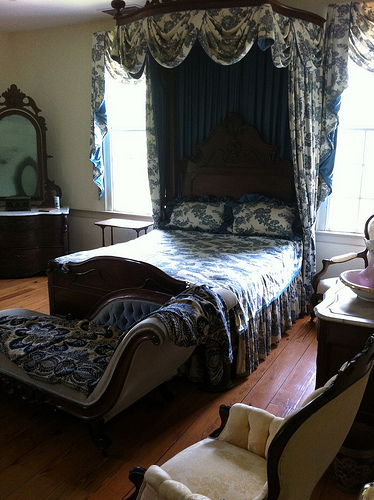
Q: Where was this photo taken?
A: A bedroom.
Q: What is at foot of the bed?
A: A chaise lounge.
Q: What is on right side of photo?
A: A cream colored chair.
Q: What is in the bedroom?
A: The dresser.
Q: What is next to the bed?
A: The window.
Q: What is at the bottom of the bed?
A: The chaise.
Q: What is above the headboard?
A: Fabric.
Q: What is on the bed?
A: Two pillows.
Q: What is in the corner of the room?
A: The vanity.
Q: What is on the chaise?
A: The blanket.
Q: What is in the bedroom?
A: The dressing table.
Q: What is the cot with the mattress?
A: Wooden.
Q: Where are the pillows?
A: On the bed.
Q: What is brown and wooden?
A: The floor.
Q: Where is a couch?
A: In front of a bed.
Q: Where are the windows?
A: On both sides of the bed.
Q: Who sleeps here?
A: Woman.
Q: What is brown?
A: Floor.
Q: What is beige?
A: Chair.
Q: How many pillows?
A: Two.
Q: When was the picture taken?
A: During the day.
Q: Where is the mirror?
A: To the left of the picture.